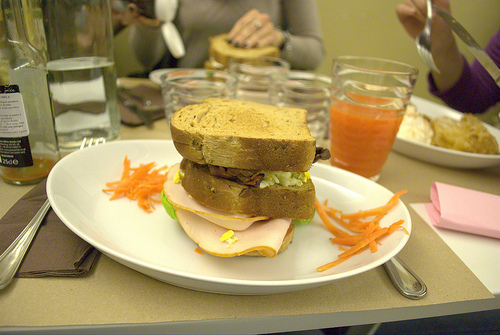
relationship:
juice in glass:
[326, 94, 403, 181] [330, 54, 420, 181]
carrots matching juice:
[319, 192, 403, 262] [331, 90, 401, 175]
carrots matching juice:
[99, 148, 171, 215] [331, 90, 401, 175]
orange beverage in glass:
[327, 96, 399, 177] [330, 54, 420, 181]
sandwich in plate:
[169, 94, 314, 223] [46, 138, 411, 295]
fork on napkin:
[6, 189, 58, 306] [8, 169, 98, 301]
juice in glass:
[328, 84, 411, 180] [330, 54, 420, 181]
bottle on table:
[3, 18, 60, 188] [6, 180, 499, 322]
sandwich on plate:
[169, 94, 314, 223] [45, 138, 412, 296]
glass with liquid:
[14, 0, 122, 153] [23, 57, 120, 148]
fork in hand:
[404, 0, 459, 74] [384, 2, 466, 101]